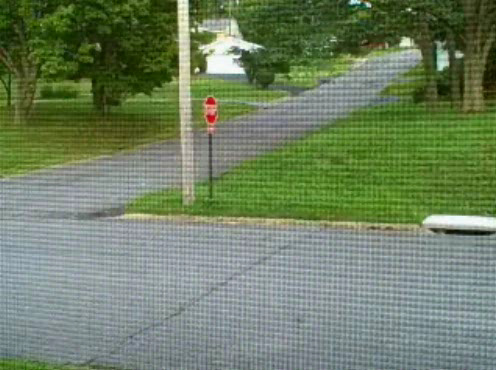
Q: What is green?
A: Grass.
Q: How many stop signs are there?
A: One.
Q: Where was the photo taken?
A: From behind a screen.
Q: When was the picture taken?
A: Daytime.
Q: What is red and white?
A: Stop sign.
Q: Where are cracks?
A: On the road.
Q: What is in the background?
A: Trees.